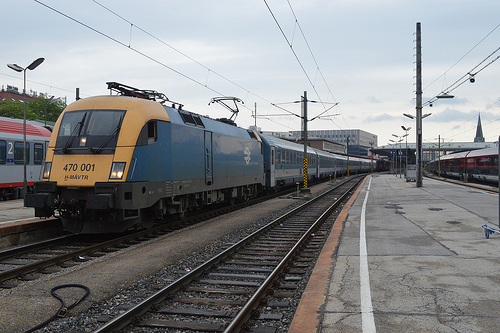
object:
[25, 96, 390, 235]
train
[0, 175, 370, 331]
tracks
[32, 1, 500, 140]
wires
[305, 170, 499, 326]
platform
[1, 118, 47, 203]
train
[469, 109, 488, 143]
spire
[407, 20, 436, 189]
pole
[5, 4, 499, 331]
scene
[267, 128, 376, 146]
building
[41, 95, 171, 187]
yellow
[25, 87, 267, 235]
train engine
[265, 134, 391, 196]
cars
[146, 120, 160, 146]
window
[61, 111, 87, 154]
wipers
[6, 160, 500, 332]
station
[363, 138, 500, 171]
station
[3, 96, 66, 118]
foliage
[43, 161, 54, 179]
lights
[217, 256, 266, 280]
wood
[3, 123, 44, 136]
red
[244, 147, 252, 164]
logo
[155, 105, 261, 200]
side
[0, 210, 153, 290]
track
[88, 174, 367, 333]
tracks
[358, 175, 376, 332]
line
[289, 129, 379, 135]
flat roof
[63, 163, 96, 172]
numbers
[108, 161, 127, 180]
light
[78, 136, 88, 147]
headlight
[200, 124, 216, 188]
door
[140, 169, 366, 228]
wheel section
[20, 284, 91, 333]
cable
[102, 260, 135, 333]
ground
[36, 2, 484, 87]
sky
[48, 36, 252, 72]
clouds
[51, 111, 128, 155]
windows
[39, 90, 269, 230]
engine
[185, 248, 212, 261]
gravel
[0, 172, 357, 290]
railing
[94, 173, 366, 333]
railing